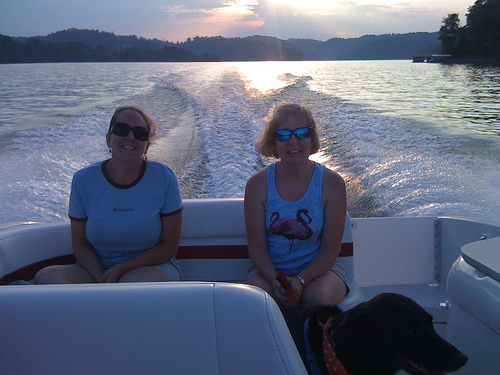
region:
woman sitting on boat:
[237, 94, 359, 308]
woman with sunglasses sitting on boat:
[34, 95, 189, 282]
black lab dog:
[278, 283, 470, 373]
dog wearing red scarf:
[271, 276, 471, 373]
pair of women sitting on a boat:
[27, 86, 362, 316]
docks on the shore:
[407, 51, 458, 68]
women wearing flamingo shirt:
[235, 98, 350, 312]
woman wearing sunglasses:
[33, 98, 184, 290]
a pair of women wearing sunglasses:
[38, 102, 355, 303]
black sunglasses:
[105, 121, 152, 141]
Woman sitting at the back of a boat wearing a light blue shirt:
[44, 76, 189, 258]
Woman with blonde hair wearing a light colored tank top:
[216, 97, 362, 262]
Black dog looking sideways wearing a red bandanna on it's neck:
[304, 289, 466, 373]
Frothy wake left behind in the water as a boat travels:
[138, 58, 280, 176]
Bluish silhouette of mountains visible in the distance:
[51, 25, 423, 58]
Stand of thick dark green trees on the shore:
[418, 5, 498, 70]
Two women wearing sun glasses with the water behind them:
[52, 100, 339, 175]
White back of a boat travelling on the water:
[10, 205, 462, 297]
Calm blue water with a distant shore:
[7, 48, 121, 103]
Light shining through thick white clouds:
[181, 0, 351, 37]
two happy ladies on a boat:
[66, 98, 348, 273]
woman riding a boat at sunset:
[65, 0, 377, 260]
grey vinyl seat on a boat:
[5, 280, 298, 372]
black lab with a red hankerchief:
[295, 294, 471, 374]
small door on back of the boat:
[350, 209, 447, 292]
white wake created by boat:
[165, 64, 257, 194]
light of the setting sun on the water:
[199, 60, 331, 94]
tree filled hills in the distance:
[24, 19, 239, 58]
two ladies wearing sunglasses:
[80, 103, 337, 226]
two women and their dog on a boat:
[26, 55, 463, 373]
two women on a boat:
[49, 92, 355, 335]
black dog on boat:
[282, 290, 460, 374]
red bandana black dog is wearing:
[317, 323, 349, 369]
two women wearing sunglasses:
[65, 100, 348, 302]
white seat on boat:
[1, 278, 306, 367]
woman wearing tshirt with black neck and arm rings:
[52, 108, 194, 273]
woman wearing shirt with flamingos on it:
[230, 105, 368, 312]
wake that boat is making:
[59, 52, 433, 199]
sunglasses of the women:
[104, 120, 311, 141]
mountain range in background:
[3, 20, 478, 60]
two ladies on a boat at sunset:
[27, 12, 415, 244]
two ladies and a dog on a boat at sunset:
[43, 43, 470, 370]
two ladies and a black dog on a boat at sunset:
[42, 60, 469, 374]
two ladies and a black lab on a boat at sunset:
[43, 54, 468, 373]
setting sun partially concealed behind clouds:
[200, 0, 367, 51]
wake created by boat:
[159, 74, 254, 196]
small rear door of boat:
[350, 216, 440, 282]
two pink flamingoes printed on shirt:
[267, 206, 316, 256]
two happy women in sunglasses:
[69, 81, 346, 293]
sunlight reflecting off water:
[220, 59, 295, 80]